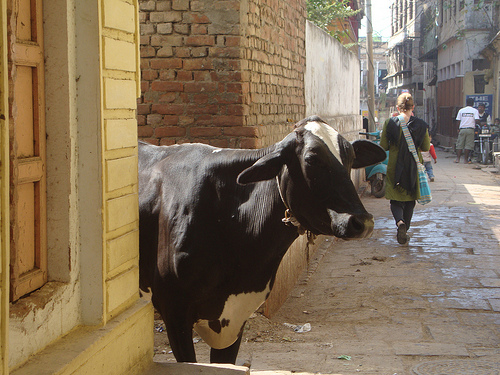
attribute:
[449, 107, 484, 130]
shirt — white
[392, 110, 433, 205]
bag — striped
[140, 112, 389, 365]
cow — black, white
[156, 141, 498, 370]
street — cobblestone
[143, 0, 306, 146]
wall — red brick